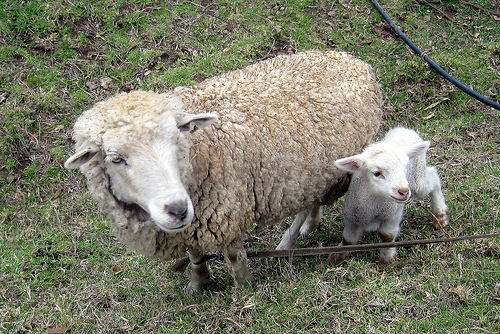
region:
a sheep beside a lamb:
[59, 45, 459, 293]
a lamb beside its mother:
[296, 101, 471, 268]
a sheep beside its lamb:
[51, 71, 428, 283]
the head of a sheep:
[66, 105, 219, 237]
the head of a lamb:
[326, 138, 433, 204]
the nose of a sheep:
[143, 190, 198, 237]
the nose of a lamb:
[386, 176, 412, 203]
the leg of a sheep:
[217, 242, 252, 288]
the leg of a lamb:
[376, 217, 402, 265]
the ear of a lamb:
[331, 148, 362, 177]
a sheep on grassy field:
[40, 50, 461, 291]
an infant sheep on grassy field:
[328, 127, 468, 273]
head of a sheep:
[36, 88, 227, 235]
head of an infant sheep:
[326, 139, 433, 203]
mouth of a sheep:
[148, 183, 198, 240]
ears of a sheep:
[165, 93, 225, 141]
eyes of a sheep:
[97, 137, 132, 184]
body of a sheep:
[170, 55, 392, 222]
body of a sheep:
[385, 129, 442, 178]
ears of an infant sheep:
[329, 144, 366, 177]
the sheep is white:
[347, 152, 462, 254]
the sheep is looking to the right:
[341, 135, 477, 266]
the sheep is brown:
[103, 63, 373, 250]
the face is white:
[105, 131, 195, 231]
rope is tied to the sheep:
[198, 236, 498, 276]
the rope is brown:
[256, 239, 489, 251]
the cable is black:
[376, 15, 496, 101]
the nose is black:
[163, 199, 194, 226]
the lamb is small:
[343, 141, 478, 277]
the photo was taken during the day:
[8, 5, 497, 321]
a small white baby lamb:
[322, 125, 455, 254]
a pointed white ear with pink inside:
[334, 154, 368, 180]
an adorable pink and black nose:
[389, 183, 411, 201]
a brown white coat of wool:
[220, 79, 327, 199]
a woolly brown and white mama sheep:
[65, 43, 381, 297]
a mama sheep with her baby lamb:
[64, 49, 457, 293]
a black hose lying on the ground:
[368, 0, 498, 102]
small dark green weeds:
[6, 2, 77, 57]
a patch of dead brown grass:
[15, 279, 146, 331]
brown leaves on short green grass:
[425, 3, 498, 51]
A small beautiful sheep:
[355, 134, 455, 241]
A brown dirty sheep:
[70, 99, 337, 284]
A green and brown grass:
[395, 252, 472, 332]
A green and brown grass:
[265, 279, 365, 332]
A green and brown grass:
[69, 248, 195, 318]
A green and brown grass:
[5, 136, 83, 295]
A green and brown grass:
[450, 125, 490, 292]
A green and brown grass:
[6, 12, 95, 146]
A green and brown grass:
[119, 12, 276, 62]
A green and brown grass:
[392, 11, 499, 45]